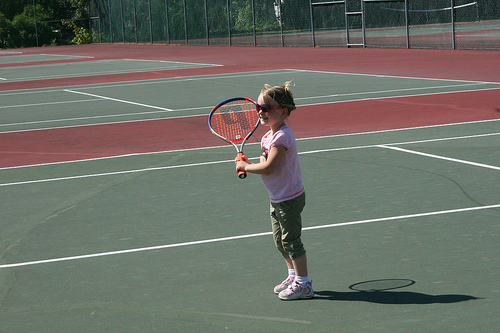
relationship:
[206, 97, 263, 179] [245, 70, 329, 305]
racket held by girl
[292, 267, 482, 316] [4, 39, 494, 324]
girl's shadow on ground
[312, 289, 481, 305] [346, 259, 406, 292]
girl's shadow of racket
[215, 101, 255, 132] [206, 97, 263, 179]
'p' on racket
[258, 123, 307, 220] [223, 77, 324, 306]
pink shirt of girl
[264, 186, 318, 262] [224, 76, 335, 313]
green pants of girl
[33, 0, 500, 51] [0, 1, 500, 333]
fence separating court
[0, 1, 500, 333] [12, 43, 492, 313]
court of court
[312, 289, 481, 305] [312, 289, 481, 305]
girl's shadow of girl's shadow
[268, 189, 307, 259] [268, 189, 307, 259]
green pants of green pants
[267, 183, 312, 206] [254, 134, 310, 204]
edge of top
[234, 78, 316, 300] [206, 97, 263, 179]
girl holding racket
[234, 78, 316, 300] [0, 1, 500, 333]
girl standing on court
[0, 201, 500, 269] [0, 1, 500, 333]
line on court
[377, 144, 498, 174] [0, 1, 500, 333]
line on court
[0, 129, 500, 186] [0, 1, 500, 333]
line on court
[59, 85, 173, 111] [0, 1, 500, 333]
line on court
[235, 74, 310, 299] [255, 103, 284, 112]
girl wearing girl's sunglasses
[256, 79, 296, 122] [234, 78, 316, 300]
hair on girl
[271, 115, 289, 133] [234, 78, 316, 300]
neck on girl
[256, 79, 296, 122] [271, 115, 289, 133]
hair off neck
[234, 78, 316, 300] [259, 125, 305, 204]
girl wearing pink shirt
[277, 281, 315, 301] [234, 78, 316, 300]
shoes on girl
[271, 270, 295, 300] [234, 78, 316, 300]
tennis shoe on girl